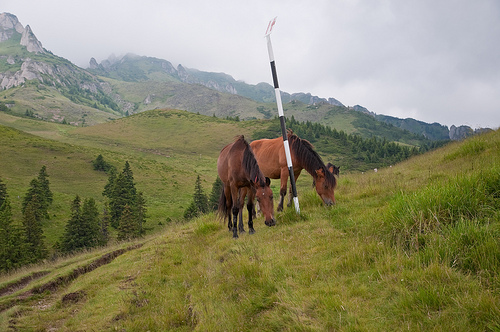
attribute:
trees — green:
[2, 153, 191, 269]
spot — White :
[258, 182, 274, 204]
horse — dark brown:
[211, 136, 276, 233]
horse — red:
[247, 134, 338, 210]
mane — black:
[288, 132, 337, 182]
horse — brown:
[250, 128, 337, 212]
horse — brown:
[218, 132, 275, 235]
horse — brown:
[314, 159, 339, 187]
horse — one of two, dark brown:
[213, 138, 280, 220]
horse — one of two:
[256, 127, 318, 188]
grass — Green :
[81, 228, 260, 313]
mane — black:
[242, 145, 266, 185]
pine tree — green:
[115, 186, 147, 243]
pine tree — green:
[106, 156, 138, 229]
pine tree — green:
[78, 195, 103, 250]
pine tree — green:
[54, 183, 88, 255]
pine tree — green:
[19, 193, 48, 263]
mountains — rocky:
[0, 0, 499, 148]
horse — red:
[249, 130, 335, 208]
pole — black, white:
[260, 14, 300, 218]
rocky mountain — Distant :
[1, 14, 106, 122]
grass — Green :
[42, 253, 232, 318]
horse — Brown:
[186, 118, 301, 250]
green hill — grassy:
[62, 129, 498, 329]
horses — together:
[220, 135, 340, 236]